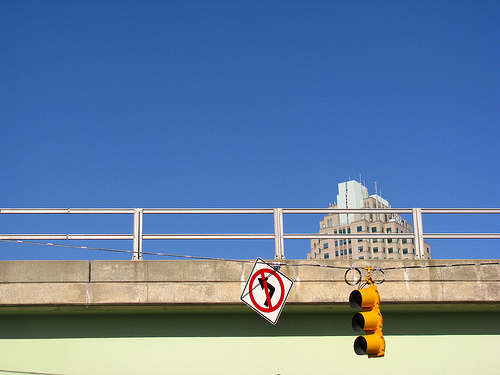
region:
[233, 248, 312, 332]
sign hanging on bridge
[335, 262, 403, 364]
yellow traffic light hanging from wire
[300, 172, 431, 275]
bridge in front of building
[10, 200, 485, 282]
bridge has metal railing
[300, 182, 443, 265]
building has windows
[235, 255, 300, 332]
sign is red and white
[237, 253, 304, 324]
do not turn sign hanging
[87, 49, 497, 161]
sky is a deep blue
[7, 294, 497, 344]
shadow cast on side of bridge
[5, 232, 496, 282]
long black wire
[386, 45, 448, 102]
part of the sky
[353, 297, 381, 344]
part of a traffic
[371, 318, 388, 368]
edge of a traffic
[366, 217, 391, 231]
part of a building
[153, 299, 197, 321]
edge of a bridge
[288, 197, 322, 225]
part of a metal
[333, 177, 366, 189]
edge of a building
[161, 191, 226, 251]
part of a balcony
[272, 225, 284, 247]
part of a post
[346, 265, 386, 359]
yellow street light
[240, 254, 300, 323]
white,red and black street sign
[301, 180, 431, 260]
building with lots of windows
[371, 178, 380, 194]
white pole on left side of building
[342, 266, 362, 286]
black circular wire in front of yellow light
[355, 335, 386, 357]
bottom part of yellow light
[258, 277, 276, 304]
black arrow on sign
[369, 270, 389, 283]
circular wire behind light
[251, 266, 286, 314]
red circle on sign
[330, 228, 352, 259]
cluster of windows on building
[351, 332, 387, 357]
Bottom segment of a yellow signal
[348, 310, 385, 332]
Middle segment of a yellow signal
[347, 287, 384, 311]
Top segment of a yellow signal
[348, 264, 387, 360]
Traffic signal hanging in the air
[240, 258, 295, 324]
Red, white and black traffic sign indicating no left turn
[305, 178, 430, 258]
Large commercial building behind a bridge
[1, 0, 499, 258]
Dark blue clear sky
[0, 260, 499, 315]
Concrete portion of a city bridge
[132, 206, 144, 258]
Vertical post in the railing of a city bridge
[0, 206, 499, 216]
Uppermost horizontal bar of a city bridge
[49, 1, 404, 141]
sky is blue and cloudless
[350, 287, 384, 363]
traffic light is yellow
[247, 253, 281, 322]
sign indicates no left turn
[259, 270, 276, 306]
arrow is black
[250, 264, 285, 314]
struck-out circle is red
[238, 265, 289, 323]
sign is white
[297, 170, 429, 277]
building is brown and green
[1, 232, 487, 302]
bridge is light brown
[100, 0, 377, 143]
sky is clear and blue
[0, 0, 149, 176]
sky is bright blue